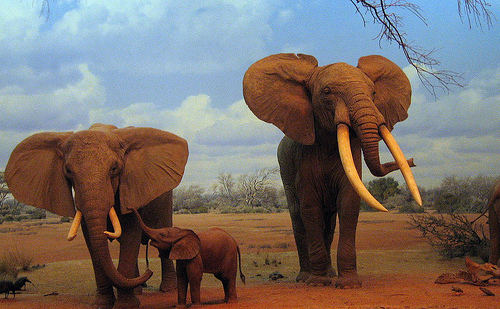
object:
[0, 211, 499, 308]
dirt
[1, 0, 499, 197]
sky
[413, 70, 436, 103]
branch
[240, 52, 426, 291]
elephant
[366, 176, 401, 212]
trees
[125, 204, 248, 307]
elephant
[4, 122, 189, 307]
elephant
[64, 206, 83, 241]
tusk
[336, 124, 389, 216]
tusk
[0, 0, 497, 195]
clouds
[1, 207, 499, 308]
ground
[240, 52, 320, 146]
ear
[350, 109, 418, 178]
trunk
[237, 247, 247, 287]
tail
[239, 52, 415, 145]
head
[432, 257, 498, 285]
bones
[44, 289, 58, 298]
twigs